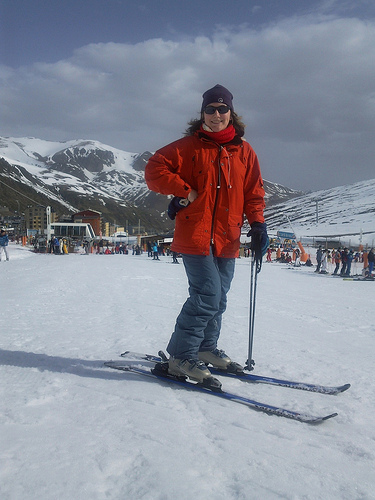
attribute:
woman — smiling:
[145, 85, 268, 382]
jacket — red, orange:
[144, 135, 266, 257]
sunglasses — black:
[204, 103, 230, 115]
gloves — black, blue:
[168, 194, 267, 256]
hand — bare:
[187, 191, 199, 203]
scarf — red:
[194, 125, 238, 143]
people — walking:
[2, 229, 182, 265]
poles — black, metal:
[245, 251, 257, 370]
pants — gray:
[166, 245, 233, 361]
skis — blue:
[101, 349, 349, 426]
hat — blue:
[201, 85, 231, 108]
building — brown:
[73, 208, 104, 244]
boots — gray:
[167, 347, 231, 381]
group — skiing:
[267, 244, 374, 282]